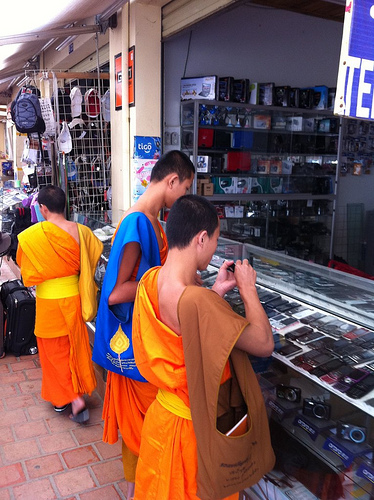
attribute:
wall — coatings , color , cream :
[99, 3, 168, 226]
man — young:
[130, 193, 274, 499]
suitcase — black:
[1, 280, 37, 352]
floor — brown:
[19, 427, 171, 488]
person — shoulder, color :
[14, 185, 96, 417]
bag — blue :
[93, 213, 164, 382]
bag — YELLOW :
[78, 225, 102, 321]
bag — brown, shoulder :
[172, 279, 274, 497]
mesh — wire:
[22, 69, 114, 227]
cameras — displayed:
[294, 386, 336, 430]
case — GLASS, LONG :
[198, 138, 353, 297]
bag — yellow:
[171, 278, 280, 489]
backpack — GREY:
[10, 87, 46, 135]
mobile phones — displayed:
[296, 270, 372, 385]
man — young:
[90, 149, 195, 497]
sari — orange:
[16, 224, 95, 390]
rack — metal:
[35, 62, 141, 253]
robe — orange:
[88, 213, 169, 461]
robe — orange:
[128, 270, 240, 498]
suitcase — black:
[2, 273, 41, 362]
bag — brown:
[173, 295, 283, 495]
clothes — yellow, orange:
[19, 222, 103, 400]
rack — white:
[19, 71, 109, 221]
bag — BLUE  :
[104, 228, 155, 387]